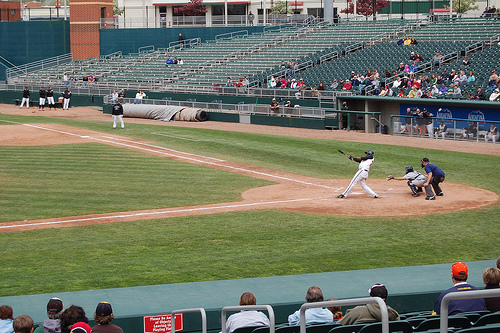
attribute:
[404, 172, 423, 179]
shirt — Gray 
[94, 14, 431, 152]
stadium — large 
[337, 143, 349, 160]
bat — Black 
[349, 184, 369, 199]
home plate — White 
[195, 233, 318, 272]
grass — green 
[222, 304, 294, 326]
shirt — White 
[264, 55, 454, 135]
seats — green 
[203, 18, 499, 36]
empty seats — empty 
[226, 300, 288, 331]
shirt — blue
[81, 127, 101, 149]
base — first 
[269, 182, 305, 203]
dirt — brown 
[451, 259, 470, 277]
cap — red, bright 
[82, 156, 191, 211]
turf — astro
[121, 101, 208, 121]
tarp — rolled up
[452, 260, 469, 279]
orange hat — orange 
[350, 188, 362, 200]
plate — home 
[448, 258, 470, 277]
cap — Orange 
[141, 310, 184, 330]
sign — White , red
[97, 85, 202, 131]
rolls — long